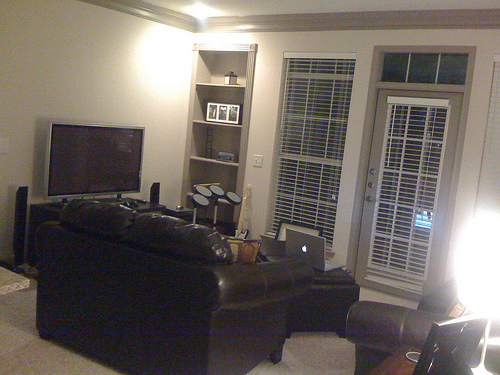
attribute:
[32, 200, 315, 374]
loveseat — black, leather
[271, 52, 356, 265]
blinds — white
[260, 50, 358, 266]
window — long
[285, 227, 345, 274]
laptop — apple, open, apple brand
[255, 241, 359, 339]
ottoman — black, leather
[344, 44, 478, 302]
door — glass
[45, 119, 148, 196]
tv — large, flat screen, wide screen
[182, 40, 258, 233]
shelves — built in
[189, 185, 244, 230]
drums — digital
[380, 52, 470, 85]
windows — small